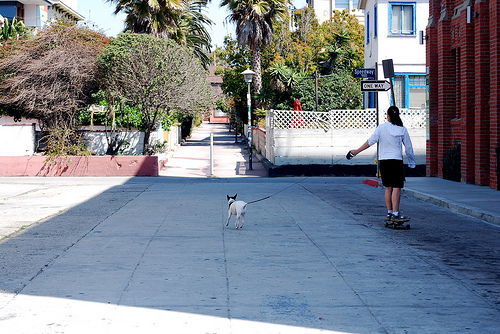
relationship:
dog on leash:
[226, 194, 253, 229] [226, 152, 355, 208]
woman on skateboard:
[354, 102, 417, 234] [377, 209, 409, 230]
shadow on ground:
[4, 172, 495, 320] [1, 178, 493, 333]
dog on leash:
[217, 190, 252, 234] [249, 142, 354, 207]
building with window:
[363, 0, 430, 109] [391, 2, 413, 34]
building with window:
[363, 0, 430, 109] [394, 76, 404, 108]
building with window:
[363, 0, 430, 109] [408, 74, 427, 85]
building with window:
[363, 0, 430, 109] [407, 84, 430, 109]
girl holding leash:
[349, 106, 415, 218] [245, 150, 355, 203]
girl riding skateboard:
[349, 106, 415, 218] [384, 215, 412, 229]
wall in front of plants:
[0, 152, 160, 178] [0, 17, 223, 154]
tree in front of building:
[1, 23, 111, 155] [424, 1, 499, 189]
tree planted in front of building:
[92, 32, 214, 155] [424, 1, 499, 189]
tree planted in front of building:
[218, 0, 289, 124] [424, 1, 499, 189]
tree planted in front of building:
[113, 0, 186, 46] [424, 1, 499, 189]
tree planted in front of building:
[305, 7, 367, 77] [424, 1, 499, 189]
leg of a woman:
[381, 185, 391, 212] [348, 105, 416, 224]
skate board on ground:
[378, 200, 419, 226] [30, 175, 484, 331]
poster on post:
[244, 97, 254, 107] [240, 85, 257, 172]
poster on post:
[246, 123, 254, 130] [240, 85, 257, 172]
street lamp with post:
[230, 61, 259, 176] [240, 85, 257, 172]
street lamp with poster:
[230, 61, 259, 176] [244, 97, 254, 107]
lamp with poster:
[236, 67, 253, 90] [246, 123, 254, 130]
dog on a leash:
[221, 191, 249, 230] [225, 147, 365, 212]